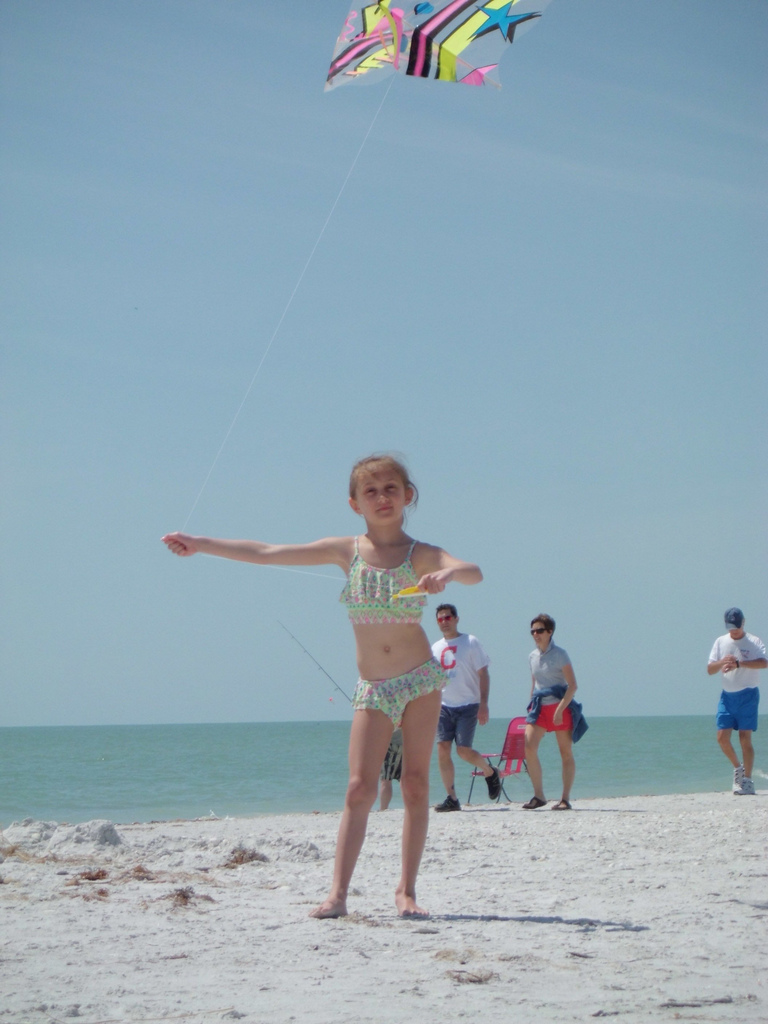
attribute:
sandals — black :
[516, 797, 570, 812]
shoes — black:
[430, 772, 506, 813]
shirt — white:
[428, 635, 485, 709]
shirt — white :
[705, 634, 766, 692]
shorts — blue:
[715, 687, 759, 729]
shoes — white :
[726, 761, 756, 797]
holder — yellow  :
[390, 573, 434, 612]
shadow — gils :
[339, 899, 668, 954]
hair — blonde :
[346, 452, 433, 506]